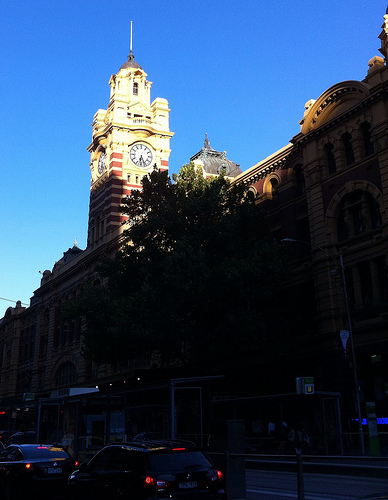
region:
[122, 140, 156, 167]
Clock on a tower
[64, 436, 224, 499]
Car driving on a road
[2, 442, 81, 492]
Car driving on a road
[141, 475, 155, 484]
Red tail light on a car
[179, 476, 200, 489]
License plate on a car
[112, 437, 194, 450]
Luggage rack on a car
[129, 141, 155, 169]
A clock on a tower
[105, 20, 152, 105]
A steeple on a rooftop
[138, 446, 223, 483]
A car's red break lights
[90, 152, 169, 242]
Red stripes on a building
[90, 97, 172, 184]
An analog clock tower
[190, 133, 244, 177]
A gray roof top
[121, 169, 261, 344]
A tree top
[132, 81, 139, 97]
A small clocktower window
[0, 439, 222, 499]
Two cars in the street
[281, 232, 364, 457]
A tall light pole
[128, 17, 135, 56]
the white spire of a building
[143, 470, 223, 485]
red brake lights on a car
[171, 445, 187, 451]
a red brake light bar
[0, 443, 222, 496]
two small black cars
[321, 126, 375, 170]
three arches on a building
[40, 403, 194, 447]
a glass store front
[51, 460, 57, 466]
the bmw emblem on a car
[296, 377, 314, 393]
a traffic light over a walkway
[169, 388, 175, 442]
a gray metal pole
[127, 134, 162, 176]
Clock on a tower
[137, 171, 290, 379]
tree in front of a building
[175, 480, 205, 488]
license plate on a truck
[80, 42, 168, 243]
tower on a building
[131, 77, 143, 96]
window in the tower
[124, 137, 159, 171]
clock on a tower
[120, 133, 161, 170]
clock on a tower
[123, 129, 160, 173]
clock on a tower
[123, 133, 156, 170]
clock on a tower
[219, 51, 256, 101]
Clear skies in the photo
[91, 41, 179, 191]
A tall building in the city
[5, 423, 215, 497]
Cars on the road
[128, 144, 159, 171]
Clock on top of the building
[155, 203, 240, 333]
Trees growing on the roadside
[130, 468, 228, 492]
Rear lights on the car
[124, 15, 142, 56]
A mast on the building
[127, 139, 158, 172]
the clock is white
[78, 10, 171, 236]
the tower has a clock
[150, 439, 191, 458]
the light on a car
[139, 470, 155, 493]
the tail light on a car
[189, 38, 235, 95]
a view of sky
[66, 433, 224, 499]
a view of car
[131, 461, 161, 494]
a view of lights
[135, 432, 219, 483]
a view of glass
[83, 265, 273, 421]
a view of trees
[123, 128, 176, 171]
a view of clock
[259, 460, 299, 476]
a view of fence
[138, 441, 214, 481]
the back window of a black car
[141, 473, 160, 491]
the tail light of a black car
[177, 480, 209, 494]
the license plate of a black car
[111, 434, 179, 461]
the roof of a black car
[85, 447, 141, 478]
the side window of a black car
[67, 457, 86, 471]
the side mirror of a black car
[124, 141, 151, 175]
The tall tower has a clock on it.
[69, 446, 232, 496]
A dark colored car is driving down the road.